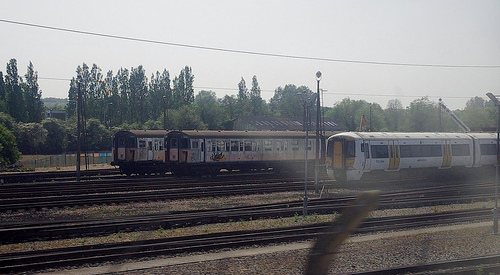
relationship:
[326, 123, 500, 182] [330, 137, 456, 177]
trains has doors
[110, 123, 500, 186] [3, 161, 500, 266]
trains on tracks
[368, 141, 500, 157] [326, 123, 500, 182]
windows on trains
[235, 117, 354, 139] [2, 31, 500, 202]
building in distance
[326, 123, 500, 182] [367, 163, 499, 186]
trains has wheels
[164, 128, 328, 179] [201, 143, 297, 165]
train has graffiti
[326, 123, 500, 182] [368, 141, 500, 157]
trains has windows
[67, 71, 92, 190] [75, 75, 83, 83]
pole has light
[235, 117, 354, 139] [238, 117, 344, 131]
building has roof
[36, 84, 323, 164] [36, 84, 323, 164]
trees behind fence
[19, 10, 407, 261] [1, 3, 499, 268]
photo taken daytime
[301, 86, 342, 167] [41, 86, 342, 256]
post along tracks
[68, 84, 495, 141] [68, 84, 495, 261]
trees along tracks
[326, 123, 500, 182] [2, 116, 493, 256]
trains on tracks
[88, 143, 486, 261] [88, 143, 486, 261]
tracks beside car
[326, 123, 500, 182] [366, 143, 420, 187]
trains has door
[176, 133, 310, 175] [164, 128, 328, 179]
graffiti on side of train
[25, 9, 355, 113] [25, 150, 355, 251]
sky above of tracks